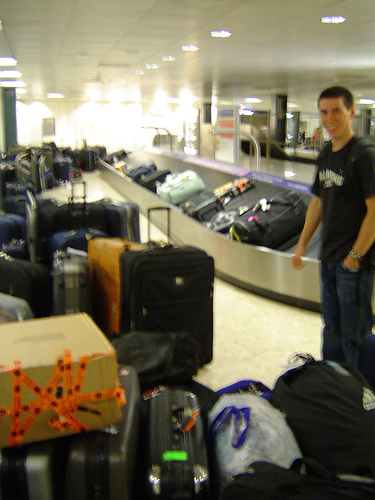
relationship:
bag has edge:
[163, 328, 204, 389] [159, 326, 193, 361]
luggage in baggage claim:
[118, 206, 213, 364] [0, 104, 371, 494]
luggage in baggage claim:
[230, 186, 307, 250] [0, 104, 371, 494]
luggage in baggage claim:
[53, 247, 91, 318] [0, 104, 371, 494]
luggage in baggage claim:
[118, 206, 213, 369] [1, 129, 296, 493]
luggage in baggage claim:
[118, 206, 213, 369] [0, 140, 375, 500]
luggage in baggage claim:
[230, 186, 307, 250] [0, 140, 375, 500]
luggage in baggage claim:
[203, 391, 305, 475] [95, 144, 325, 310]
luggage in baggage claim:
[118, 206, 213, 369] [13, 158, 257, 434]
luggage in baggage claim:
[118, 206, 213, 369] [13, 161, 225, 401]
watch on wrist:
[347, 247, 365, 261] [345, 246, 364, 259]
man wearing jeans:
[290, 86, 373, 390] [314, 253, 374, 388]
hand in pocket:
[286, 252, 303, 273] [336, 265, 362, 291]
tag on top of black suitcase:
[160, 446, 193, 462] [146, 388, 212, 497]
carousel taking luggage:
[97, 145, 320, 314] [230, 186, 307, 250]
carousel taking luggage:
[97, 145, 320, 314] [181, 189, 225, 220]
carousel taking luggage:
[97, 145, 320, 314] [156, 168, 204, 204]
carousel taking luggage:
[97, 145, 320, 314] [139, 167, 172, 190]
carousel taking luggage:
[97, 145, 320, 314] [125, 160, 155, 178]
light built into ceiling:
[0, 55, 18, 66] [0, 0, 374, 111]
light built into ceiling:
[0, 69, 23, 79] [0, 0, 374, 111]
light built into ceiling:
[0, 79, 25, 88] [0, 0, 374, 111]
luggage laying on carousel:
[155, 169, 204, 205] [111, 138, 325, 250]